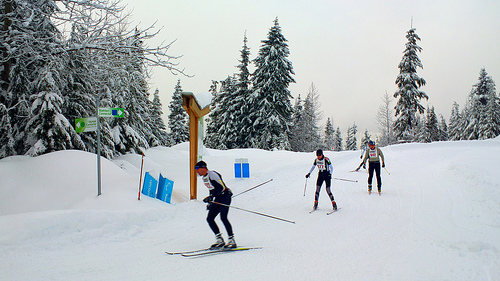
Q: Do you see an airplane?
A: No, there are no airplanes.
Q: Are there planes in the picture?
A: No, there are no planes.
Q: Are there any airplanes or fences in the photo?
A: No, there are no airplanes or fences.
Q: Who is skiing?
A: The skier is skiing.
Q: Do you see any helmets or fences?
A: No, there are no fences or helmets.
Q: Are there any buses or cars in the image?
A: No, there are no cars or buses.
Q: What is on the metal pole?
A: The sign is on the pole.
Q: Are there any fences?
A: No, there are no fences.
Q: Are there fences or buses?
A: No, there are no fences or buses.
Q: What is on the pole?
A: The sign is on the pole.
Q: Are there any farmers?
A: No, there are no farmers.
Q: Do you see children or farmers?
A: No, there are no farmers or children.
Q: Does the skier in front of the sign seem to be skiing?
A: Yes, the skier is skiing.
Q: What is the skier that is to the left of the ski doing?
A: The skier is skiing.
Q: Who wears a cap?
A: The skier wears a cap.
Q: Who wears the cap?
A: The skier wears a cap.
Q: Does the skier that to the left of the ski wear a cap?
A: Yes, the skier wears a cap.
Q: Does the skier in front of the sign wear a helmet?
A: No, the skier wears a cap.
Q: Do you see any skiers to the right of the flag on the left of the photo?
A: Yes, there is a skier to the right of the flag.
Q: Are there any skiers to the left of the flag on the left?
A: No, the skier is to the right of the flag.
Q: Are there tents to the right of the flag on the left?
A: No, there is a skier to the right of the flag.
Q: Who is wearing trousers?
A: The skier is wearing trousers.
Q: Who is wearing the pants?
A: The skier is wearing trousers.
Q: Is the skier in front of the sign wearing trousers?
A: Yes, the skier is wearing trousers.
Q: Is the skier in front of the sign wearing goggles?
A: No, the skier is wearing trousers.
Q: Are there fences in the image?
A: No, there are no fences.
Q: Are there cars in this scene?
A: No, there are no cars.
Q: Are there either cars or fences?
A: No, there are no cars or fences.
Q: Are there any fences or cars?
A: No, there are no cars or fences.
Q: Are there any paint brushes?
A: No, there are no paint brushes.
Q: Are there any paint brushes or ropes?
A: No, there are no paint brushes or ropes.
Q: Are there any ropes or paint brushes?
A: No, there are no paint brushes or ropes.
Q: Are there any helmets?
A: No, there are no helmets.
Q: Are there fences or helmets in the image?
A: No, there are no helmets or fences.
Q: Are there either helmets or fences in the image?
A: No, there are no helmets or fences.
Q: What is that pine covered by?
A: The pine is covered by the snow.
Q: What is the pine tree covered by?
A: The pine is covered by the snow.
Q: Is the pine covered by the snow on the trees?
A: Yes, the pine is covered by the snow.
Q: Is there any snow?
A: Yes, there is snow.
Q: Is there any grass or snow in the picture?
A: Yes, there is snow.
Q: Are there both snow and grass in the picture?
A: No, there is snow but no grass.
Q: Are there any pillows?
A: No, there are no pillows.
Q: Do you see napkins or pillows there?
A: No, there are no pillows or napkins.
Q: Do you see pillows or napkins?
A: No, there are no pillows or napkins.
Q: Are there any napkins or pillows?
A: No, there are no pillows or napkins.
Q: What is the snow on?
A: The snow is on the trees.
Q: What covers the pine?
A: The snow covers the pine.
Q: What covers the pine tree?
A: The snow covers the pine.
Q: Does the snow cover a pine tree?
A: Yes, the snow covers a pine tree.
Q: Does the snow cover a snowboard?
A: No, the snow covers a pine tree.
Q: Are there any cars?
A: No, there are no cars.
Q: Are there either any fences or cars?
A: No, there are no cars or fences.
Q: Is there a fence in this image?
A: No, there are no fences.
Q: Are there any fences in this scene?
A: No, there are no fences.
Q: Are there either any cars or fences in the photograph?
A: No, there are no fences or cars.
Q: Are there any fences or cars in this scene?
A: No, there are no fences or cars.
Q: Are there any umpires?
A: No, there are no umpires.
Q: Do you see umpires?
A: No, there are no umpires.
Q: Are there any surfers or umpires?
A: No, there are no umpires or surfers.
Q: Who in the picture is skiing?
A: The skier is skiing.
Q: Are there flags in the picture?
A: Yes, there is a flag.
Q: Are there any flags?
A: Yes, there is a flag.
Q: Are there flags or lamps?
A: Yes, there is a flag.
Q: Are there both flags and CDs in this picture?
A: No, there is a flag but no cds.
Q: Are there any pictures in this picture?
A: No, there are no pictures.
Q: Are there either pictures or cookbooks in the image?
A: No, there are no pictures or cookbooks.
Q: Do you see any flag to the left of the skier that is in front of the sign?
A: Yes, there is a flag to the left of the skier.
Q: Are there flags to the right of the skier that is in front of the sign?
A: No, the flag is to the left of the skier.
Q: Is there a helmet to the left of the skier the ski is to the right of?
A: No, there is a flag to the left of the skier.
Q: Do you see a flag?
A: Yes, there is a flag.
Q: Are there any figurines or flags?
A: Yes, there is a flag.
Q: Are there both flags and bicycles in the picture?
A: No, there is a flag but no bicycles.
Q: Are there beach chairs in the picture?
A: No, there are no beach chairs.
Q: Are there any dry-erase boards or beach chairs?
A: No, there are no beach chairs or dry-erase boards.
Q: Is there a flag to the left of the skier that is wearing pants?
A: Yes, there is a flag to the left of the skier.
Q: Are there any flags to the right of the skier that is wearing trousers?
A: No, the flag is to the left of the skier.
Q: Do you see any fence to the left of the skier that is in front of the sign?
A: No, there is a flag to the left of the skier.